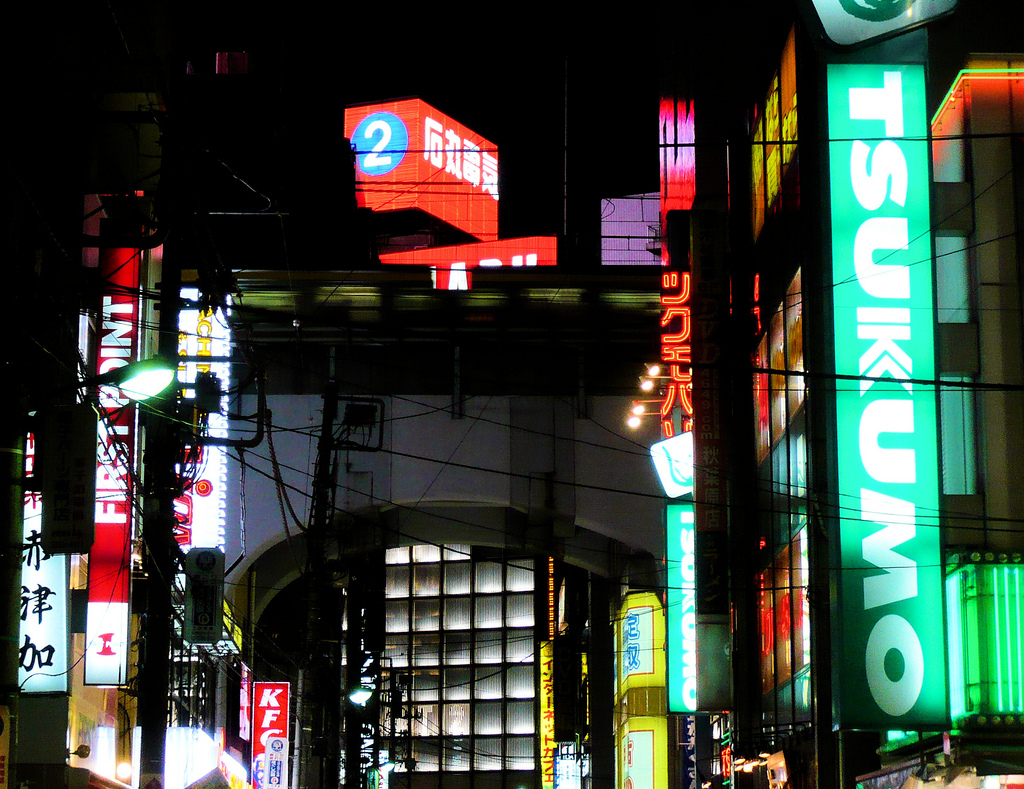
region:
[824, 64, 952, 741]
the sign is green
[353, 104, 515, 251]
the sign is red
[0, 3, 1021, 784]
the lights are bright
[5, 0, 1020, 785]
is is dark outdoors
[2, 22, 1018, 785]
the scene takes place outdoors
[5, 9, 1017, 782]
the scene is a city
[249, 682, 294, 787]
kfc sign is bright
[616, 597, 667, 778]
the sign is yellow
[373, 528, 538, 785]
the windows are lit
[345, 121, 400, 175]
the number two is blue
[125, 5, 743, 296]
the sky is dark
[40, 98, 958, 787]
all the lights are colorful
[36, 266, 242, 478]
the street light is on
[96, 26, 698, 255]
it is night time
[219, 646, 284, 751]
the sign is red and white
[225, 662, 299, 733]
the letters are white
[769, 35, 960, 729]
the sign is tall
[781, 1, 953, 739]
the sign is green and white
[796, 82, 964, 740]
The large green illuminated sign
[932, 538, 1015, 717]
A small neon green sign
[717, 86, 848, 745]
The huge screen of television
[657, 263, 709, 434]
The red sign in different language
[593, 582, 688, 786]
The yellow neon sign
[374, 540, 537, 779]
The screen of televisions that are off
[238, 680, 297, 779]
The sign for KFC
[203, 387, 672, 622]
The black archway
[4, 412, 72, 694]
The white sign with black chinese writing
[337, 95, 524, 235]
The sign with the number 2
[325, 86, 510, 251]
the number 2 is color white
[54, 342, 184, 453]
a light on a pole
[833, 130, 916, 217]
letter S on an advertisement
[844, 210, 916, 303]
letter U on an advertisement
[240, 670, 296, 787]
an advertisement of KFC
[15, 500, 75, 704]
black Chinese letters on an advertisement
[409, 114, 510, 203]
white letters on a red advertisement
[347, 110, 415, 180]
the number 2 on a blue circle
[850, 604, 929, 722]
letter O on an advertisement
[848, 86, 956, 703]
sign has letters on it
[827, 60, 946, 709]
letters on sign are white in color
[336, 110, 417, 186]
sign has number on it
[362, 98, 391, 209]
number on sign is white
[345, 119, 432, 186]
number on sign in blue ball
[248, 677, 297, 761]
sign is red in color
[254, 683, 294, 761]
sign has white text on it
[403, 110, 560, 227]
sign has white text on it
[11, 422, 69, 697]
white sign in front of building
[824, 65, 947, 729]
teal sign in front of building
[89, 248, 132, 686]
red and white sign in front of building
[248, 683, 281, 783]
red and white sign in front of building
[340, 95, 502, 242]
red and white sign on top of building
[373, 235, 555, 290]
red and white sign on top of building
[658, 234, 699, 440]
red sign on top of building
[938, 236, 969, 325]
window next to teal sign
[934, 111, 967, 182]
window next to teal sign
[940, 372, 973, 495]
window next to teal sign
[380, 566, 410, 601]
a window on a building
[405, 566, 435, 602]
a window on a building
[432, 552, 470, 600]
a window on a building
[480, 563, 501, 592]
a window on a building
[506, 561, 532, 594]
a window on a building